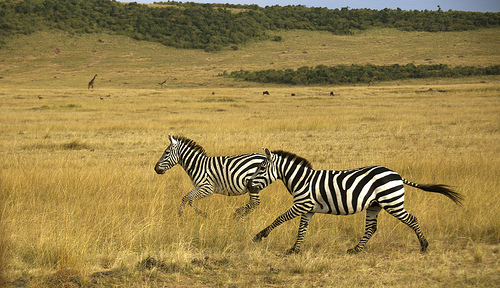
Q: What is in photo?
A: 2 black and white zebras.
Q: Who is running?
A: The zebra.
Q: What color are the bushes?
A: Green.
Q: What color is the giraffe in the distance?
A: Brown.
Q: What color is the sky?
A: Blue.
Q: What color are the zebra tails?
A: Black.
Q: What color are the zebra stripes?
A: Black.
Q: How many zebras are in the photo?
A: 2.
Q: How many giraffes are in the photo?
A: One.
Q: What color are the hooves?
A: Black.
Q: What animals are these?
A: Zebras.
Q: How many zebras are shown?
A: Two.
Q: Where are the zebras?
A: In a prairie.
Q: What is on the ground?
A: Grass.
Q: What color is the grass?
A: Yellow.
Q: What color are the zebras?
A: Black and white.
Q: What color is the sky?
A: Blue.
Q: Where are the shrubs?
A: Far behind the zebras.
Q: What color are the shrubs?
A: Green.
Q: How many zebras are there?
A: Two.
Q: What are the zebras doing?
A: Running.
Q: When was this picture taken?
A: Daytime.